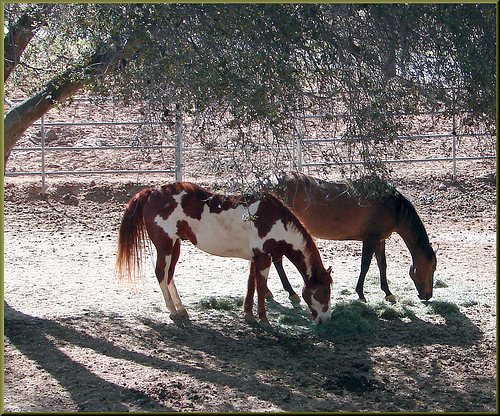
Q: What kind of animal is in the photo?
A: Horse.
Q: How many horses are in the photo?
A: Two.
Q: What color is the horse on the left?
A: Brown and white.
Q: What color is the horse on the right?
A: Brown.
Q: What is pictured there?
A: Horses.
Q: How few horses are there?
A: 2.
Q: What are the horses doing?
A: Grazing.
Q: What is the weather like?
A: Fair.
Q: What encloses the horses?
A: Fences.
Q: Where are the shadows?
A: Ground.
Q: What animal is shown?
A: Horses.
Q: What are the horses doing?
A: Eating.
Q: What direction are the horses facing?
A: Right.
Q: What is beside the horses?
A: Tree.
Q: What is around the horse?
A: Fence.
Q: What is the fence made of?
A: Metal.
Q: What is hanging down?
A: Leaves.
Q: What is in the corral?
A: Dirt.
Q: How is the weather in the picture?
A: Sunny.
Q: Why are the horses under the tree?
A: For shade.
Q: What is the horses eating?
A: Grass.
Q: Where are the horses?
A: Under a tree.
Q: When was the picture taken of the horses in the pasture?
A: Summer.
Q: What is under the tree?
A: Two red and white horses.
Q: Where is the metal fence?
A: Around the pasture.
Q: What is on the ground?
A: Green patches of grass.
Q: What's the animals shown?
A: Horses.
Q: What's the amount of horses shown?
A: Two.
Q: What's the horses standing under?
A: Tree.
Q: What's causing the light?
A: Sun.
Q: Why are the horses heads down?
A: They are eating.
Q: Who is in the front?
A: The spotted horse.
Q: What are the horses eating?
A: Grass.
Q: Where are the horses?
A: Under the tree.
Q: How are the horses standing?
A: Side to side.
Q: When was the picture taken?
A: Daytime.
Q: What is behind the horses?
A: A fence.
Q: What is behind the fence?
A: A field.